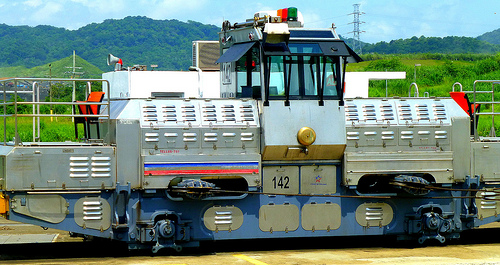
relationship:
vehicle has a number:
[2, 5, 498, 254] [266, 172, 295, 193]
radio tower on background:
[337, 1, 372, 62] [4, 0, 498, 51]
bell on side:
[292, 122, 322, 157] [113, 114, 466, 190]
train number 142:
[2, 5, 498, 254] [266, 172, 295, 193]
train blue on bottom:
[2, 5, 498, 254] [6, 187, 482, 255]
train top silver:
[2, 5, 498, 254] [2, 95, 499, 180]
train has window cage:
[2, 5, 498, 254] [211, 4, 362, 101]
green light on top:
[284, 4, 301, 24] [204, 2, 346, 41]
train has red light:
[2, 5, 498, 254] [280, 5, 290, 20]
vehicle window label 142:
[258, 160, 302, 199] [266, 172, 295, 193]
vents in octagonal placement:
[213, 208, 235, 228] [198, 203, 247, 235]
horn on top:
[101, 48, 127, 72] [95, 2, 406, 76]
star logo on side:
[312, 172, 325, 184] [113, 114, 466, 190]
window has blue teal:
[234, 45, 263, 98] [212, 40, 260, 65]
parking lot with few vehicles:
[1, 74, 54, 109] [2, 79, 34, 91]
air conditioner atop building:
[189, 38, 200, 69] [188, 37, 223, 74]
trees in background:
[375, 33, 485, 57] [4, 0, 498, 51]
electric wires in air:
[317, 11, 499, 40] [303, 0, 496, 45]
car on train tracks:
[2, 5, 498, 254] [4, 239, 492, 262]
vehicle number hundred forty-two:
[2, 5, 498, 254] [266, 172, 295, 193]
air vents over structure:
[66, 93, 497, 227] [2, 93, 500, 254]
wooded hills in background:
[3, 12, 496, 72] [4, 0, 498, 51]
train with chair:
[2, 5, 498, 254] [72, 91, 106, 140]